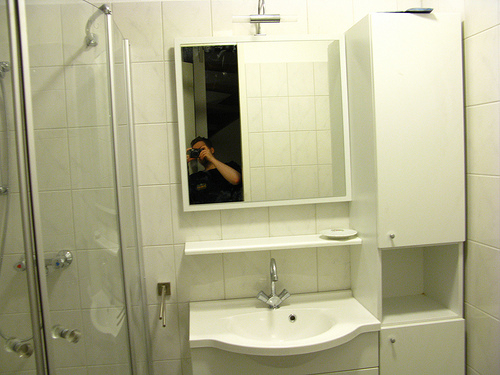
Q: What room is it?
A: It is a bathroom.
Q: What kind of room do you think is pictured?
A: It is a bathroom.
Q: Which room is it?
A: It is a bathroom.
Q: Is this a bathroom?
A: Yes, it is a bathroom.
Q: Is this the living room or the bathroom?
A: It is the bathroom.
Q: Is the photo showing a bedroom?
A: No, the picture is showing a bathroom.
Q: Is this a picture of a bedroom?
A: No, the picture is showing a bathroom.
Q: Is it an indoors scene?
A: Yes, it is indoors.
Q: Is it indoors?
A: Yes, it is indoors.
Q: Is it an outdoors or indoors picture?
A: It is indoors.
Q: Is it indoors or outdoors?
A: It is indoors.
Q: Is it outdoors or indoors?
A: It is indoors.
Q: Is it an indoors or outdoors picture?
A: It is indoors.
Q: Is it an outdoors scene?
A: No, it is indoors.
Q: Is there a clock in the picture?
A: No, there are no clocks.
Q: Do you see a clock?
A: No, there are no clocks.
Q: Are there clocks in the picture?
A: No, there are no clocks.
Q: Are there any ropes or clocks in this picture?
A: No, there are no clocks or ropes.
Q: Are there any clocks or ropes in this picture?
A: No, there are no clocks or ropes.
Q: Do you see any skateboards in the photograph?
A: No, there are no skateboards.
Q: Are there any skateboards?
A: No, there are no skateboards.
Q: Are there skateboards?
A: No, there are no skateboards.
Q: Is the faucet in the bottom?
A: Yes, the faucet is in the bottom of the image.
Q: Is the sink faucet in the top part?
A: No, the faucet is in the bottom of the image.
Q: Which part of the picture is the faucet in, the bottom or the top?
A: The faucet is in the bottom of the image.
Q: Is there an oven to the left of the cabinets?
A: No, there is a faucet to the left of the cabinets.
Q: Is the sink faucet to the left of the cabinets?
A: Yes, the tap is to the left of the cabinets.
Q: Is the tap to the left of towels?
A: No, the tap is to the left of the cabinets.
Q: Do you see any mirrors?
A: Yes, there is a mirror.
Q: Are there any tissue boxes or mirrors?
A: Yes, there is a mirror.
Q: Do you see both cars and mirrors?
A: No, there is a mirror but no cars.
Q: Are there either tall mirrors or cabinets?
A: Yes, there is a tall mirror.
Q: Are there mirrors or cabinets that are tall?
A: Yes, the mirror is tall.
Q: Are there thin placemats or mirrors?
A: Yes, there is a thin mirror.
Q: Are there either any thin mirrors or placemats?
A: Yes, there is a thin mirror.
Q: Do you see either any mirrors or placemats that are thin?
A: Yes, the mirror is thin.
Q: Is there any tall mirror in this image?
A: Yes, there is a tall mirror.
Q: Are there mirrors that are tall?
A: Yes, there is a mirror that is tall.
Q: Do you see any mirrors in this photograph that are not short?
A: Yes, there is a tall mirror.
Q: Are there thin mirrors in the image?
A: Yes, there is a thin mirror.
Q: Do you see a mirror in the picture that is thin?
A: Yes, there is a mirror that is thin.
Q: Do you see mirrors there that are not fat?
A: Yes, there is a thin mirror.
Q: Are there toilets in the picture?
A: No, there are no toilets.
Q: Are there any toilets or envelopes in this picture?
A: No, there are no toilets or envelopes.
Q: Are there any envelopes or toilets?
A: No, there are no toilets or envelopes.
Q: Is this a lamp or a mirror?
A: This is a mirror.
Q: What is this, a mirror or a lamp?
A: This is a mirror.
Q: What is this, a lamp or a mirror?
A: This is a mirror.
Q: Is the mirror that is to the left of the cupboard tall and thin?
A: Yes, the mirror is tall and thin.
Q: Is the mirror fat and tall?
A: No, the mirror is tall but thin.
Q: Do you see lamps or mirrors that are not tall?
A: No, there is a mirror but it is tall.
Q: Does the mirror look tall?
A: Yes, the mirror is tall.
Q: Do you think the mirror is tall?
A: Yes, the mirror is tall.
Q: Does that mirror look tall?
A: Yes, the mirror is tall.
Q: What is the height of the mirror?
A: The mirror is tall.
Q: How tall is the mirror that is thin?
A: The mirror is tall.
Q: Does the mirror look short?
A: No, the mirror is tall.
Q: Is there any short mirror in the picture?
A: No, there is a mirror but it is tall.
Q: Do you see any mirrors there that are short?
A: No, there is a mirror but it is tall.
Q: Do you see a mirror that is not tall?
A: No, there is a mirror but it is tall.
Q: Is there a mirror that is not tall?
A: No, there is a mirror but it is tall.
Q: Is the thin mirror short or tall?
A: The mirror is tall.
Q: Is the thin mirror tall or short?
A: The mirror is tall.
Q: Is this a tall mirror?
A: Yes, this is a tall mirror.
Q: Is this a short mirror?
A: No, this is a tall mirror.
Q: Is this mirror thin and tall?
A: Yes, the mirror is thin and tall.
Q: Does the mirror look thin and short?
A: No, the mirror is thin but tall.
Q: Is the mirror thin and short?
A: No, the mirror is thin but tall.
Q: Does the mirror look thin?
A: Yes, the mirror is thin.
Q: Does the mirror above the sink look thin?
A: Yes, the mirror is thin.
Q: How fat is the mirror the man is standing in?
A: The mirror is thin.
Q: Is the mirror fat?
A: No, the mirror is thin.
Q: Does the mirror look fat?
A: No, the mirror is thin.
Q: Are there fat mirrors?
A: No, there is a mirror but it is thin.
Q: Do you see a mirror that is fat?
A: No, there is a mirror but it is thin.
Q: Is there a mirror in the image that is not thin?
A: No, there is a mirror but it is thin.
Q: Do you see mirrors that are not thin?
A: No, there is a mirror but it is thin.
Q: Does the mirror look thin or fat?
A: The mirror is thin.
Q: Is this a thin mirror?
A: Yes, this is a thin mirror.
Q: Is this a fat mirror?
A: No, this is a thin mirror.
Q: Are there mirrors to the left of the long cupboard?
A: Yes, there is a mirror to the left of the cupboard.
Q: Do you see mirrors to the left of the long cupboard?
A: Yes, there is a mirror to the left of the cupboard.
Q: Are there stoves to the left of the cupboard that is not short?
A: No, there is a mirror to the left of the cupboard.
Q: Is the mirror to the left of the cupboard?
A: Yes, the mirror is to the left of the cupboard.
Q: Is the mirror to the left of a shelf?
A: No, the mirror is to the left of the cupboard.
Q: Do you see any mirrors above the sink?
A: Yes, there is a mirror above the sink.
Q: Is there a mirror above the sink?
A: Yes, there is a mirror above the sink.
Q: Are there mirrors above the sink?
A: Yes, there is a mirror above the sink.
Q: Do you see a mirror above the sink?
A: Yes, there is a mirror above the sink.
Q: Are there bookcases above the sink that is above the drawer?
A: No, there is a mirror above the sink.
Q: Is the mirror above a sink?
A: Yes, the mirror is above a sink.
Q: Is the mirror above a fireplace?
A: No, the mirror is above a sink.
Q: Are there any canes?
A: No, there are no canes.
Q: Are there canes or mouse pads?
A: No, there are no canes or mouse pads.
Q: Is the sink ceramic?
A: Yes, the sink is ceramic.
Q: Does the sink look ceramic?
A: Yes, the sink is ceramic.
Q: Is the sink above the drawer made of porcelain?
A: Yes, the sink is made of porcelain.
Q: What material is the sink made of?
A: The sink is made of porcelain.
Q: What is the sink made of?
A: The sink is made of porcelain.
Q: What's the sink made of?
A: The sink is made of porcelain.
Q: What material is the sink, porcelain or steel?
A: The sink is made of porcelain.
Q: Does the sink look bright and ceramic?
A: Yes, the sink is bright and ceramic.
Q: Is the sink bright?
A: Yes, the sink is bright.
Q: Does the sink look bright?
A: Yes, the sink is bright.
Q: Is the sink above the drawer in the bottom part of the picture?
A: Yes, the sink is above the drawer.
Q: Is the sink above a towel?
A: No, the sink is above the drawer.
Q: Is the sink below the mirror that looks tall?
A: Yes, the sink is below the mirror.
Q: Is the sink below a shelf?
A: No, the sink is below the mirror.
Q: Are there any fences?
A: No, there are no fences.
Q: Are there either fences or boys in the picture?
A: No, there are no fences or boys.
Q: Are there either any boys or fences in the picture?
A: No, there are no fences or boys.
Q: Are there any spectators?
A: No, there are no spectators.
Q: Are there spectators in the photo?
A: No, there are no spectators.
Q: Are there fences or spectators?
A: No, there are no spectators or fences.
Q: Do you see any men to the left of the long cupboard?
A: Yes, there is a man to the left of the cupboard.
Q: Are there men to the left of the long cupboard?
A: Yes, there is a man to the left of the cupboard.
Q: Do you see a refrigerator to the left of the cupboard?
A: No, there is a man to the left of the cupboard.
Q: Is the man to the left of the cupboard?
A: Yes, the man is to the left of the cupboard.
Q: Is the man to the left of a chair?
A: No, the man is to the left of the cupboard.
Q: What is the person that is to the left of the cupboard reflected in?
A: The man is reflected in the mirror.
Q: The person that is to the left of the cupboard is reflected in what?
A: The man is reflected in the mirror.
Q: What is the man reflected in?
A: The man is reflected in the mirror.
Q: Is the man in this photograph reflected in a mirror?
A: Yes, the man is reflected in a mirror.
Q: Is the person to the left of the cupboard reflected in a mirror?
A: Yes, the man is reflected in a mirror.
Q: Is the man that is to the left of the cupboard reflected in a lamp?
A: No, the man is reflected in a mirror.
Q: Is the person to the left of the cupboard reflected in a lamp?
A: No, the man is reflected in a mirror.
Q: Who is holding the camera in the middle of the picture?
A: The man is holding the camera.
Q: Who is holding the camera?
A: The man is holding the camera.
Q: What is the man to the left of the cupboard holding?
A: The man is holding the camera.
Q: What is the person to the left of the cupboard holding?
A: The man is holding the camera.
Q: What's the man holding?
A: The man is holding the camera.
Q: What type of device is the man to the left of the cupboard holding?
A: The man is holding the camera.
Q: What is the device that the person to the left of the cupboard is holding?
A: The device is a camera.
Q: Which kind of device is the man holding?
A: The man is holding the camera.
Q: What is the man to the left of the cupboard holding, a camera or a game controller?
A: The man is holding a camera.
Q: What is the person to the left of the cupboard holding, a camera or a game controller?
A: The man is holding a camera.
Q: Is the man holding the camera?
A: Yes, the man is holding the camera.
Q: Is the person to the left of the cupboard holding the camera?
A: Yes, the man is holding the camera.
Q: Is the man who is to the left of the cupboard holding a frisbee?
A: No, the man is holding the camera.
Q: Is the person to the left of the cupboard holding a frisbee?
A: No, the man is holding the camera.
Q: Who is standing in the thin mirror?
A: The man is standing in the mirror.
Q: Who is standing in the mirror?
A: The man is standing in the mirror.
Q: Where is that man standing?
A: The man is standing in the mirror.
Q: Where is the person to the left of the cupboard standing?
A: The man is standing in the mirror.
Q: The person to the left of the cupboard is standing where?
A: The man is standing in the mirror.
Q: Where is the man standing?
A: The man is standing in the mirror.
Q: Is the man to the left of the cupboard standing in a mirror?
A: Yes, the man is standing in a mirror.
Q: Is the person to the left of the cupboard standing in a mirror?
A: Yes, the man is standing in a mirror.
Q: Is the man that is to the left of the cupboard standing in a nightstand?
A: No, the man is standing in a mirror.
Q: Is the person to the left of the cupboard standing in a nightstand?
A: No, the man is standing in a mirror.